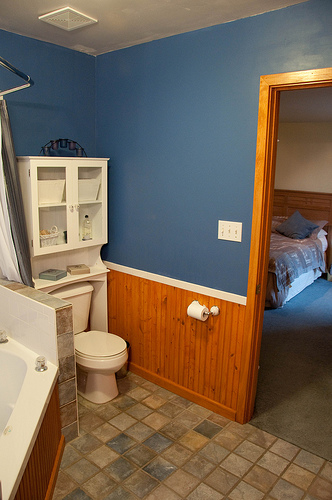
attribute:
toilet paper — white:
[185, 302, 209, 321]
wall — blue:
[96, 6, 330, 416]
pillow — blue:
[275, 211, 319, 240]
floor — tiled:
[52, 374, 330, 500]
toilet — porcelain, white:
[52, 281, 130, 402]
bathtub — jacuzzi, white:
[1, 331, 66, 498]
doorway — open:
[236, 65, 331, 459]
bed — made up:
[264, 191, 331, 308]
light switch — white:
[216, 218, 243, 244]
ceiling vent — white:
[39, 4, 98, 33]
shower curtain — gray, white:
[0, 95, 35, 286]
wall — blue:
[1, 30, 98, 157]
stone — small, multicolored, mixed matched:
[140, 412, 173, 429]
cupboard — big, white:
[15, 155, 110, 329]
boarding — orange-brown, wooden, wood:
[109, 270, 246, 416]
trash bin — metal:
[115, 343, 131, 377]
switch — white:
[234, 229, 239, 238]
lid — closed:
[74, 328, 128, 355]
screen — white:
[2, 159, 23, 283]